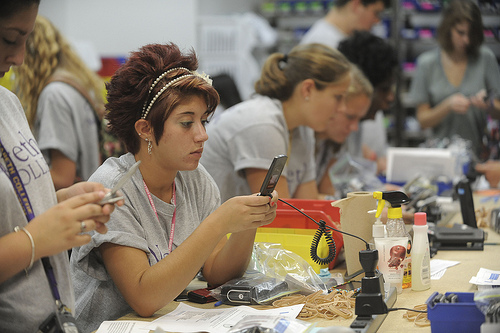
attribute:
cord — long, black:
[277, 200, 374, 272]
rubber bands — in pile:
[267, 284, 357, 324]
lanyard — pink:
[137, 172, 186, 258]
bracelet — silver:
[15, 224, 37, 289]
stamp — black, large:
[352, 245, 399, 314]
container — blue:
[407, 287, 493, 329]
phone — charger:
[251, 153, 289, 199]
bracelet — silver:
[12, 225, 35, 273]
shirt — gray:
[410, 52, 484, 137]